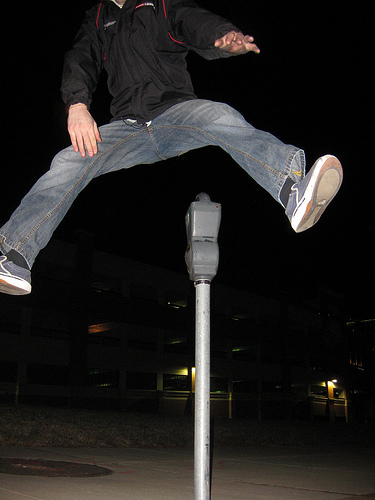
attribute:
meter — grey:
[187, 191, 221, 498]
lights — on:
[331, 376, 340, 389]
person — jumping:
[0, 0, 349, 292]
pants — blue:
[0, 103, 306, 268]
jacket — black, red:
[52, 0, 246, 123]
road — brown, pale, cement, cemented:
[0, 442, 373, 499]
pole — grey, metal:
[191, 282, 214, 498]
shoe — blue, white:
[283, 157, 343, 240]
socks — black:
[281, 175, 297, 209]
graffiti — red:
[11, 460, 66, 473]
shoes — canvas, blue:
[0, 153, 345, 299]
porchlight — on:
[184, 368, 202, 377]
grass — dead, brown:
[3, 412, 374, 446]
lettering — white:
[104, 18, 118, 34]